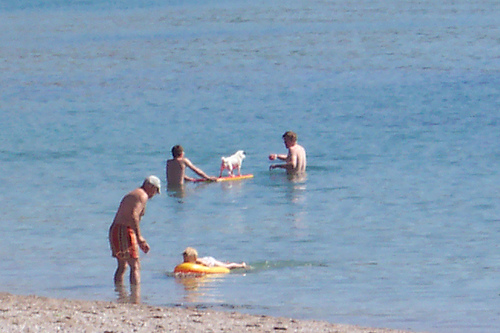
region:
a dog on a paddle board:
[212, 143, 262, 188]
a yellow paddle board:
[213, 171, 273, 182]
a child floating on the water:
[163, 243, 262, 274]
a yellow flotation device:
[175, 262, 233, 279]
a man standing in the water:
[109, 170, 164, 301]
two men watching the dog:
[164, 122, 338, 195]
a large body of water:
[3, 42, 492, 317]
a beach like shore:
[2, 290, 418, 332]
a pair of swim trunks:
[108, 219, 143, 261]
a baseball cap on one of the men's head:
[138, 171, 167, 196]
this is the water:
[108, 56, 244, 121]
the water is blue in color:
[61, 59, 195, 116]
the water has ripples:
[316, 25, 398, 84]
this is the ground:
[33, 308, 85, 330]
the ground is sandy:
[12, 300, 71, 331]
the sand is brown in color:
[16, 310, 108, 330]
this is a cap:
[142, 171, 167, 193]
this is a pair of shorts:
[108, 229, 143, 260]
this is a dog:
[211, 144, 251, 174]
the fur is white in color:
[224, 155, 239, 165]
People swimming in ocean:
[109, 128, 306, 310]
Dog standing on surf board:
[211, 143, 256, 188]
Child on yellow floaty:
[175, 246, 252, 277]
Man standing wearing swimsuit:
[110, 169, 159, 286]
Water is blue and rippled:
[1, 1, 498, 331]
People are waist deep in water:
[163, 129, 314, 184]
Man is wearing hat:
[137, 171, 164, 198]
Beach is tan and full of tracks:
[1, 290, 396, 332]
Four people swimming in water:
[100, 121, 307, 291]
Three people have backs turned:
[108, 131, 308, 292]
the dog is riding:
[190, 118, 277, 209]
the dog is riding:
[192, 130, 314, 260]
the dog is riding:
[217, 152, 277, 253]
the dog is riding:
[220, 150, 258, 192]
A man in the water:
[264, 128, 311, 184]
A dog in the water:
[213, 145, 250, 172]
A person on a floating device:
[176, 243, 259, 273]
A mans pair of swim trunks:
[101, 211, 151, 269]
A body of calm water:
[342, 88, 485, 265]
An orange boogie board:
[204, 173, 259, 183]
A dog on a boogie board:
[206, 143, 256, 188]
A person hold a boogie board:
[153, 138, 223, 193]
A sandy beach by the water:
[26, 300, 143, 328]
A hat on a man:
[132, 176, 175, 195]